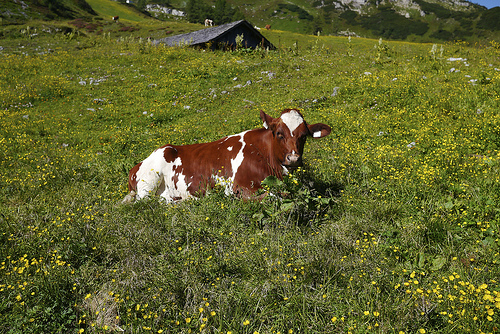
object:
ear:
[307, 123, 331, 139]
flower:
[361, 307, 371, 317]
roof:
[157, 18, 281, 51]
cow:
[120, 108, 331, 207]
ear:
[259, 109, 272, 128]